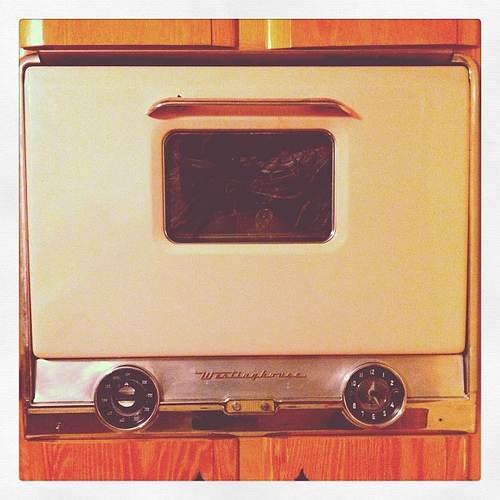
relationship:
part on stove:
[167, 131, 334, 244] [21, 50, 476, 433]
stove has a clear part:
[21, 50, 476, 433] [167, 131, 334, 244]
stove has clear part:
[21, 50, 476, 433] [167, 131, 334, 244]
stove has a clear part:
[21, 50, 476, 433] [162, 127, 337, 247]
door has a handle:
[26, 67, 465, 354] [149, 96, 362, 122]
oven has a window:
[22, 47, 478, 435] [161, 126, 337, 245]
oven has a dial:
[22, 47, 478, 435] [92, 362, 163, 433]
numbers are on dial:
[99, 372, 154, 425] [92, 362, 163, 433]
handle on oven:
[149, 96, 362, 122] [22, 47, 478, 435]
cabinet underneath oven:
[23, 437, 482, 481] [22, 47, 478, 435]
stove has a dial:
[21, 50, 476, 433] [92, 362, 163, 433]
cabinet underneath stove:
[23, 437, 482, 481] [21, 50, 476, 433]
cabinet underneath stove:
[263, 432, 482, 483] [21, 50, 476, 433]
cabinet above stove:
[21, 19, 240, 54] [21, 50, 476, 433]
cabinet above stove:
[264, 14, 479, 50] [21, 50, 476, 433]